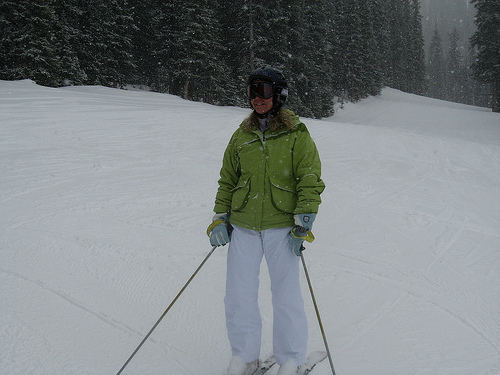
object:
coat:
[211, 108, 324, 231]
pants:
[222, 218, 307, 363]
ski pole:
[297, 245, 342, 374]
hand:
[287, 217, 314, 241]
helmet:
[245, 64, 289, 91]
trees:
[163, 4, 221, 101]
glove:
[206, 218, 235, 246]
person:
[204, 67, 324, 375]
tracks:
[334, 244, 440, 295]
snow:
[1, 80, 499, 375]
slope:
[395, 99, 485, 133]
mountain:
[0, 51, 499, 375]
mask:
[244, 82, 279, 101]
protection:
[436, 17, 444, 23]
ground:
[0, 68, 499, 374]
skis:
[274, 345, 326, 374]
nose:
[252, 96, 261, 101]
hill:
[0, 56, 499, 374]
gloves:
[289, 212, 315, 254]